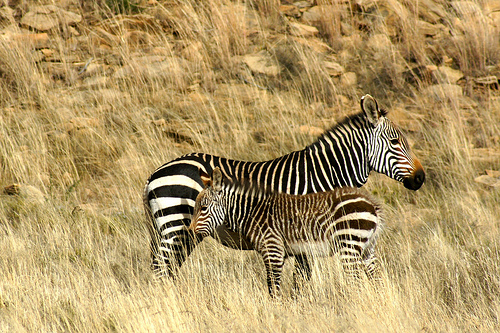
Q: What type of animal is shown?
A: Zebra.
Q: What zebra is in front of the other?
A: Baby.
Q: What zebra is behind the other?
A: Adult.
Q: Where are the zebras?
A: In grass field.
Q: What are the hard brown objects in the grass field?
A: Rocks.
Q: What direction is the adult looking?
A: Right.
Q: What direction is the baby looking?
A: Left.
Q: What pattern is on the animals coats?
A: Stripes.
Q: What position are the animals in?
A: Standing.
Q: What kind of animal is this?
A: Zebra.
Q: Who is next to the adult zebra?
A: Baby zebra.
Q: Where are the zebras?
A: Field.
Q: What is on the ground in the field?
A: Yellowed grass.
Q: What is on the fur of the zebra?
A: Striped pattern.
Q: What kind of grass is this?
A: Yellowed tall grass.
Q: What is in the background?
A: Mountain.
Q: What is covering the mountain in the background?
A: Rocks.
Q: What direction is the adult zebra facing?
A: Right.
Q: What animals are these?
A: Zebras.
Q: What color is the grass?
A: Yellow.